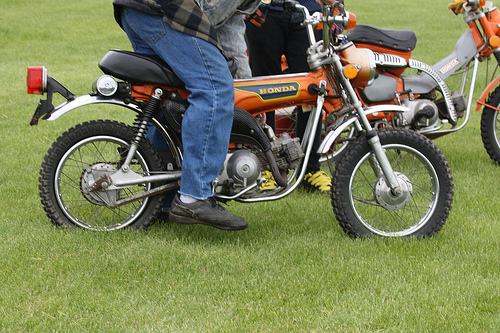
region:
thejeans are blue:
[187, 60, 239, 197]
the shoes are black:
[170, 188, 251, 226]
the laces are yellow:
[307, 164, 332, 194]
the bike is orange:
[95, 46, 445, 249]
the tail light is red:
[25, 66, 50, 91]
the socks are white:
[172, 188, 198, 205]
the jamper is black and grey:
[164, 3, 216, 33]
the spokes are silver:
[58, 134, 154, 226]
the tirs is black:
[352, 125, 462, 246]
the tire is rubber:
[339, 135, 448, 244]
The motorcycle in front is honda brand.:
[240, 72, 302, 102]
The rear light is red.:
[10, 55, 52, 95]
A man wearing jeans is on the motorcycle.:
[113, 9, 240, 201]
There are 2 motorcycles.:
[253, 55, 478, 220]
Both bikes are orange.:
[267, 22, 492, 161]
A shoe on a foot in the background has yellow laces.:
[299, 163, 335, 198]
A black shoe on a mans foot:
[161, 184, 254, 244]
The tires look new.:
[327, 122, 462, 274]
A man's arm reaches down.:
[203, 7, 303, 144]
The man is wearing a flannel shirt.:
[169, 0, 216, 41]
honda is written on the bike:
[233, 75, 300, 103]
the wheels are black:
[313, 115, 458, 255]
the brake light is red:
[7, 53, 63, 107]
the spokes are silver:
[365, 152, 425, 220]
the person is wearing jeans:
[110, 0, 234, 204]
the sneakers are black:
[118, 167, 258, 257]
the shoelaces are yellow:
[281, 155, 330, 197]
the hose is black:
[256, 131, 296, 193]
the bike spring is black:
[125, 84, 181, 154]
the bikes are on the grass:
[9, 0, 430, 311]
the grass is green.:
[50, 203, 285, 296]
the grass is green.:
[213, 288, 289, 330]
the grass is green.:
[168, 223, 287, 309]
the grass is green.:
[203, 261, 322, 308]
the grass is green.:
[211, 232, 348, 289]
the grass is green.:
[131, 189, 240, 256]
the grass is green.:
[163, 255, 253, 310]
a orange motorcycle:
[31, 21, 402, 248]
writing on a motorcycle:
[231, 71, 319, 111]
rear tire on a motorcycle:
[28, 96, 188, 242]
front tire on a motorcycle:
[297, 107, 459, 260]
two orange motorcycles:
[36, 2, 494, 239]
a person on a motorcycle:
[42, 6, 279, 253]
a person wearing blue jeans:
[147, 39, 248, 268]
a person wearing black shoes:
[148, 155, 248, 245]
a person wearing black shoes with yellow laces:
[297, 150, 332, 210]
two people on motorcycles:
[75, 13, 397, 238]